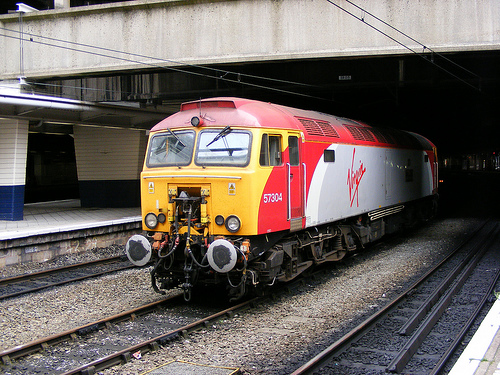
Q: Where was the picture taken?
A: At a train station.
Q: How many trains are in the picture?
A: 1.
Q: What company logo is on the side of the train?
A: Virgin.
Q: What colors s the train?
A: Red, yellow, and white.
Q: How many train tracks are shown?
A: 3.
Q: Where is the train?
A: Under the bridge.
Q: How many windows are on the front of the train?
A: 2.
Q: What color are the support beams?
A: White and blue.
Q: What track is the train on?
A: The middle track.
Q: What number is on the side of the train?
A: 57304.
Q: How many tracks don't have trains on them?
A: 2.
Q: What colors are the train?
A: White, yellow and red.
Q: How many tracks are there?
A: 3.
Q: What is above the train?
A: Powerlines.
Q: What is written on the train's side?
A: Virgin.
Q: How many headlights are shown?
A: 4.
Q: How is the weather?
A: Calm.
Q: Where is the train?
A: On train tracks.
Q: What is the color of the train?
A: White, red, yellow.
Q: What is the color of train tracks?
A: Black.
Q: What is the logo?
A: Virgin.